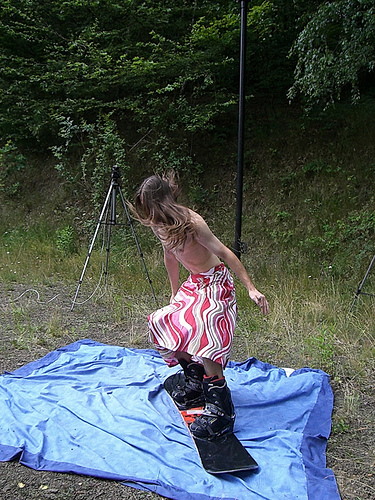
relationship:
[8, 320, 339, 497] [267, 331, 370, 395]
blanket on ground